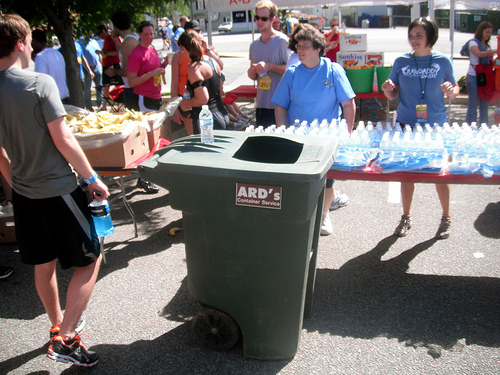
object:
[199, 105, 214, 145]
water bottle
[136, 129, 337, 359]
bin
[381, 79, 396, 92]
hand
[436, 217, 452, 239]
foot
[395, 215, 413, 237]
foot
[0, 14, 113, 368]
man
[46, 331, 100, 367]
shoe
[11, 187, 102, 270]
shorts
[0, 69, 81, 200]
shirt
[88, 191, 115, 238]
bottle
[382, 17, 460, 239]
woman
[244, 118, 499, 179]
table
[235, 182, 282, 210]
company name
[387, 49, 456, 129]
shirt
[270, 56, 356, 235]
shirt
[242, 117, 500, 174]
bottles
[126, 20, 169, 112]
woman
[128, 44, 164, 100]
shirt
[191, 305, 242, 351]
wheel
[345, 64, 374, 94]
pail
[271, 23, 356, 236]
woman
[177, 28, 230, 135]
woman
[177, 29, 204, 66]
brown hair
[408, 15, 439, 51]
her hair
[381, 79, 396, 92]
her hand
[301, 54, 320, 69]
sexy neck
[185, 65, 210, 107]
arm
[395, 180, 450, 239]
legs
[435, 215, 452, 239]
sneakers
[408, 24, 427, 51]
smiling face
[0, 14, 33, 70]
head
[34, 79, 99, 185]
arm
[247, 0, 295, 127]
people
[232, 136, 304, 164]
hole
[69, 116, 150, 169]
boxes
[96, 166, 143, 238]
table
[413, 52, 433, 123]
id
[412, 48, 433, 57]
neck